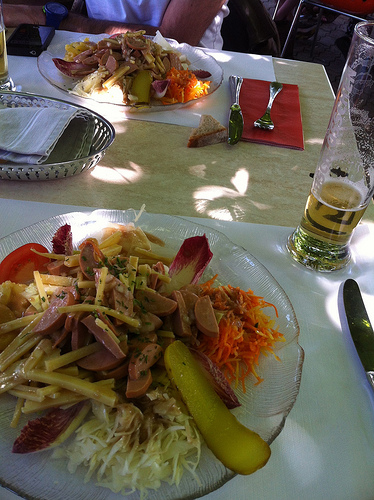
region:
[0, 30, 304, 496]
two elegant looking antipastos at an Italian restaurant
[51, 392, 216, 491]
white shredded mozzarella cheese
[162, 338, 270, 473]
dill pickle sliced in half lengthwise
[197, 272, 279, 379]
bright orange shredded carrots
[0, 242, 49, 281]
Roma plum tomato sliced in half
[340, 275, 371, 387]
silver knife laying to the right of the plate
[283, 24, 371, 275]
tall glass partially full of beer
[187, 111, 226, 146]
small triangular piece of bread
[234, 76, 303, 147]
folded red cloth napkin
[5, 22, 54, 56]
black cell phone on the table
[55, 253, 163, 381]
sliced hot dog on a plate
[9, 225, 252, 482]
food on a clear plate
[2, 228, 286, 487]
food on a clear, round plate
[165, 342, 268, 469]
green pickle on a plate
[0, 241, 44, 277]
red tomato on a plate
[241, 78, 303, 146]
fork on top of a red napkin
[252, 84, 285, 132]
silver fork on a napkin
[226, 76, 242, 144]
silver butter knife on the table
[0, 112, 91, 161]
gray napkin inside a basket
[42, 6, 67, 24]
person wearing a black watch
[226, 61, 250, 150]
knife on a table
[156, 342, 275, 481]
pickle in a bowl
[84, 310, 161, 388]
meat in a bowl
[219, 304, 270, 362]
carrots in a bowl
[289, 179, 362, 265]
beer in a glass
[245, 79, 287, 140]
fork on a table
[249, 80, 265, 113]
red napkin on a table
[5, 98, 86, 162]
towel in a basket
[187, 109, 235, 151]
bread on the table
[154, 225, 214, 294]
cabbage in a bowl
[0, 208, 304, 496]
a clear glass plate full of food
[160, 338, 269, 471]
a green pickle on the plate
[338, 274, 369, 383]
a dinner knife to the right of the plate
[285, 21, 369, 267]
tall glass with some beer in it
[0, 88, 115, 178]
a silver bread basket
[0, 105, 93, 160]
the gray napkin in the bread basket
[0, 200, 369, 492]
a white placemat the meal is on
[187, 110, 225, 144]
a bit of bread on the table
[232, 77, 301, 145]
a red napkin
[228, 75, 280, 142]
two eating utensils on the red napkin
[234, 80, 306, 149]
a red napkin on a table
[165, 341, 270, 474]
a slice of pickle on a glass plate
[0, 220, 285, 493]
a salad of various veggies and sausage in a glass plate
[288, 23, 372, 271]
an elongated glass on a table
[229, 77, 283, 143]
a fork and knife on a napkin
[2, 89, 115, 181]
a metal bread basket on a table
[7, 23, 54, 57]
a black tablet on a table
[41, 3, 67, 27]
a blue watch on a person's wrist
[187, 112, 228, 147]
a bit of bread on a table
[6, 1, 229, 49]
a person sitting at a table